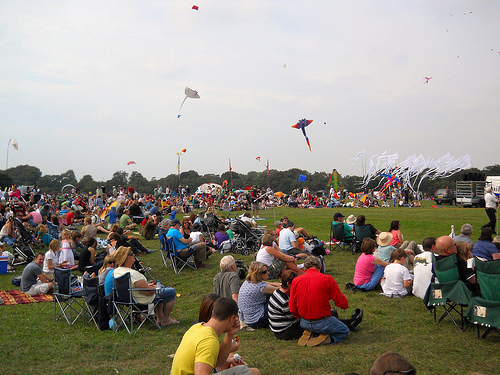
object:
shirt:
[170, 322, 220, 375]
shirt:
[288, 269, 349, 320]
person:
[169, 297, 253, 375]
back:
[170, 322, 212, 375]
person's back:
[295, 269, 330, 320]